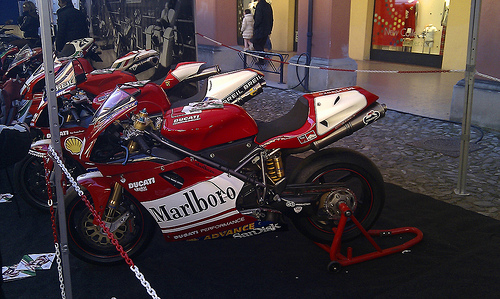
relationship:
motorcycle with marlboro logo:
[53, 82, 395, 257] [145, 182, 238, 234]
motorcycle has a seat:
[53, 82, 395, 257] [246, 91, 313, 152]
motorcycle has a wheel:
[53, 82, 395, 257] [274, 137, 392, 249]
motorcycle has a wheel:
[53, 82, 395, 257] [282, 145, 387, 244]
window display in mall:
[369, 0, 452, 78] [0, 2, 499, 298]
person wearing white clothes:
[240, 7, 259, 50] [234, 14, 255, 50]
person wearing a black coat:
[252, 0, 275, 67] [247, 2, 276, 40]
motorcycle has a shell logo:
[11, 55, 272, 214] [61, 133, 86, 157]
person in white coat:
[240, 7, 259, 50] [237, 13, 260, 41]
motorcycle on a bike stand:
[53, 82, 395, 257] [311, 199, 428, 280]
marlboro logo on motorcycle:
[145, 182, 238, 234] [53, 82, 395, 257]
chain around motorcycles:
[189, 30, 468, 79] [1, 26, 392, 270]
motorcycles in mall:
[1, 26, 392, 270] [0, 2, 499, 298]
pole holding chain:
[451, 2, 484, 199] [189, 30, 468, 79]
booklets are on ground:
[2, 248, 60, 290] [0, 46, 499, 296]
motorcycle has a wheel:
[11, 55, 272, 214] [282, 145, 387, 244]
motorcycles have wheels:
[1, 26, 392, 270] [12, 135, 396, 267]